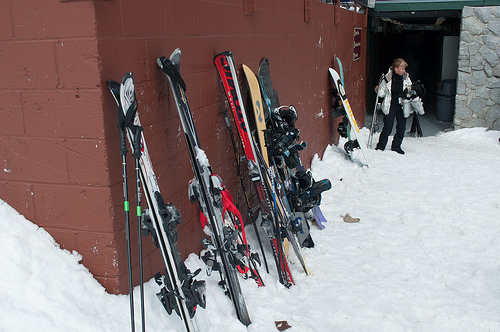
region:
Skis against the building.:
[81, 40, 294, 328]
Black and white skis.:
[95, 60, 205, 329]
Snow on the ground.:
[277, 173, 462, 288]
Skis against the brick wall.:
[161, 47, 370, 324]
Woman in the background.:
[319, 25, 479, 167]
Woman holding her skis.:
[350, 37, 440, 159]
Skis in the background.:
[287, 32, 392, 174]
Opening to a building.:
[360, 7, 476, 141]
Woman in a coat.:
[370, 53, 435, 148]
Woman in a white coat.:
[365, 39, 444, 194]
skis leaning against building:
[114, 49, 361, 307]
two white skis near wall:
[101, 75, 199, 319]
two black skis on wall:
[162, 53, 282, 298]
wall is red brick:
[92, 6, 202, 103]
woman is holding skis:
[369, 47, 431, 151]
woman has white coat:
[377, 63, 424, 119]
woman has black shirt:
[373, 68, 424, 119]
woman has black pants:
[361, 89, 421, 151]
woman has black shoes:
[345, 132, 421, 152]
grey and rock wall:
[454, 18, 499, 132]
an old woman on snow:
[352, 41, 442, 168]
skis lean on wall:
[87, 22, 387, 327]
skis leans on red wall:
[14, 3, 366, 330]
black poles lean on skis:
[100, 69, 188, 330]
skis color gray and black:
[107, 59, 211, 330]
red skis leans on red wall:
[215, 48, 253, 293]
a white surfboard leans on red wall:
[325, 58, 375, 175]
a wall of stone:
[445, 5, 497, 135]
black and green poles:
[117, 146, 152, 330]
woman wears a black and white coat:
[367, 48, 432, 150]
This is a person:
[375, 55, 419, 156]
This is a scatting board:
[321, 40, 371, 187]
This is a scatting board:
[103, 65, 153, 325]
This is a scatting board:
[157, 31, 252, 330]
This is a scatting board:
[206, 29, 280, 321]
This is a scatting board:
[280, 86, 332, 277]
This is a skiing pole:
[361, 66, 382, 170]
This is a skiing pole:
[114, 111, 131, 328]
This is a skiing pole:
[129, 99, 148, 328]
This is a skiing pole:
[216, 86, 278, 323]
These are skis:
[95, 95, 321, 288]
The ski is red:
[218, 84, 293, 211]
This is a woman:
[373, 57, 435, 200]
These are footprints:
[392, 179, 467, 286]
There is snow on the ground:
[410, 234, 432, 291]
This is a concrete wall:
[87, 126, 103, 148]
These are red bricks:
[86, 146, 116, 206]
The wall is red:
[90, 177, 117, 232]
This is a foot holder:
[267, 127, 289, 169]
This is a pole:
[127, 159, 159, 206]